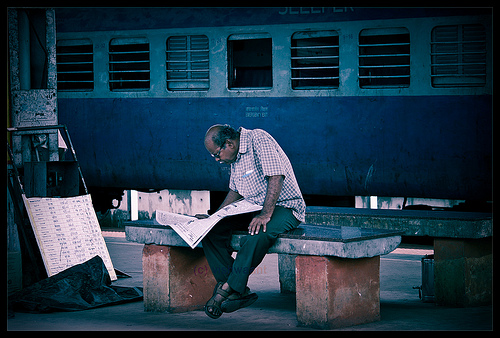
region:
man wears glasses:
[181, 105, 292, 190]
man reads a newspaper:
[140, 154, 281, 251]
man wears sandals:
[187, 261, 271, 326]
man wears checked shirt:
[188, 109, 305, 221]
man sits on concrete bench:
[204, 211, 358, 306]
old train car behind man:
[88, 21, 347, 183]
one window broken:
[173, 23, 305, 113]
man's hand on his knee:
[230, 186, 302, 272]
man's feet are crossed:
[193, 254, 279, 321]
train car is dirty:
[69, 55, 198, 180]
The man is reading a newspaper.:
[190, 124, 287, 312]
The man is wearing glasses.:
[201, 148, 229, 163]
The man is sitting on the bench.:
[144, 189, 385, 312]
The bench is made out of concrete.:
[138, 223, 379, 323]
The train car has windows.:
[85, 40, 323, 102]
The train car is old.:
[68, 31, 473, 150]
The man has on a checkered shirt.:
[247, 141, 317, 222]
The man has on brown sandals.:
[207, 274, 265, 327]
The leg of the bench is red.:
[299, 261, 394, 326]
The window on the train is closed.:
[168, 36, 214, 100]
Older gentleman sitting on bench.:
[201, 118, 301, 318]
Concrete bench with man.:
[122, 220, 409, 330]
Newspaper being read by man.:
[154, 196, 267, 248]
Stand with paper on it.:
[19, 188, 116, 280]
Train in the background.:
[26, 23, 490, 203]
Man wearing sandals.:
[204, 282, 258, 321]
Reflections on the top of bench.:
[282, 221, 400, 246]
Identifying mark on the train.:
[241, 103, 276, 121]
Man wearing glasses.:
[201, 126, 243, 166]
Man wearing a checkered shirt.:
[224, 123, 308, 220]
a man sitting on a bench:
[112, 70, 379, 323]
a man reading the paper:
[143, 86, 368, 336]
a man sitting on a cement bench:
[103, 73, 385, 337]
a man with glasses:
[132, 97, 394, 279]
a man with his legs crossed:
[167, 132, 337, 337]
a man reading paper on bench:
[99, 70, 334, 328]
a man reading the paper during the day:
[103, 67, 356, 334]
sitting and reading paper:
[167, 75, 353, 302]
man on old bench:
[117, 86, 385, 316]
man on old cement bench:
[79, 91, 404, 334]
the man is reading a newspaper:
[138, 87, 319, 305]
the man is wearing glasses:
[156, 103, 286, 190]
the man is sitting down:
[133, 105, 414, 322]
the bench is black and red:
[128, 211, 441, 329]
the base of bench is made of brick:
[124, 220, 389, 335]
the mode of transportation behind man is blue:
[56, 14, 488, 238]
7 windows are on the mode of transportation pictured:
[55, 3, 493, 194]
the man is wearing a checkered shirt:
[216, 122, 320, 225]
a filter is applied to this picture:
[4, 3, 484, 319]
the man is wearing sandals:
[184, 268, 270, 333]